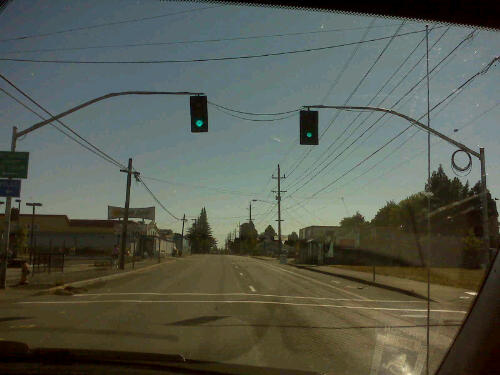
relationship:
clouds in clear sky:
[166, 162, 241, 214] [0, 0, 498, 250]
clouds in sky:
[166, 162, 241, 214] [0, 0, 499, 206]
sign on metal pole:
[0, 150, 29, 180] [117, 150, 144, 273]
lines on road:
[19, 286, 469, 307] [50, 174, 475, 354]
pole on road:
[102, 163, 152, 268] [26, 240, 455, 370]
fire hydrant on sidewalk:
[14, 261, 34, 285] [3, 258, 120, 288]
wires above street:
[267, 29, 479, 191] [0, 247, 470, 362]